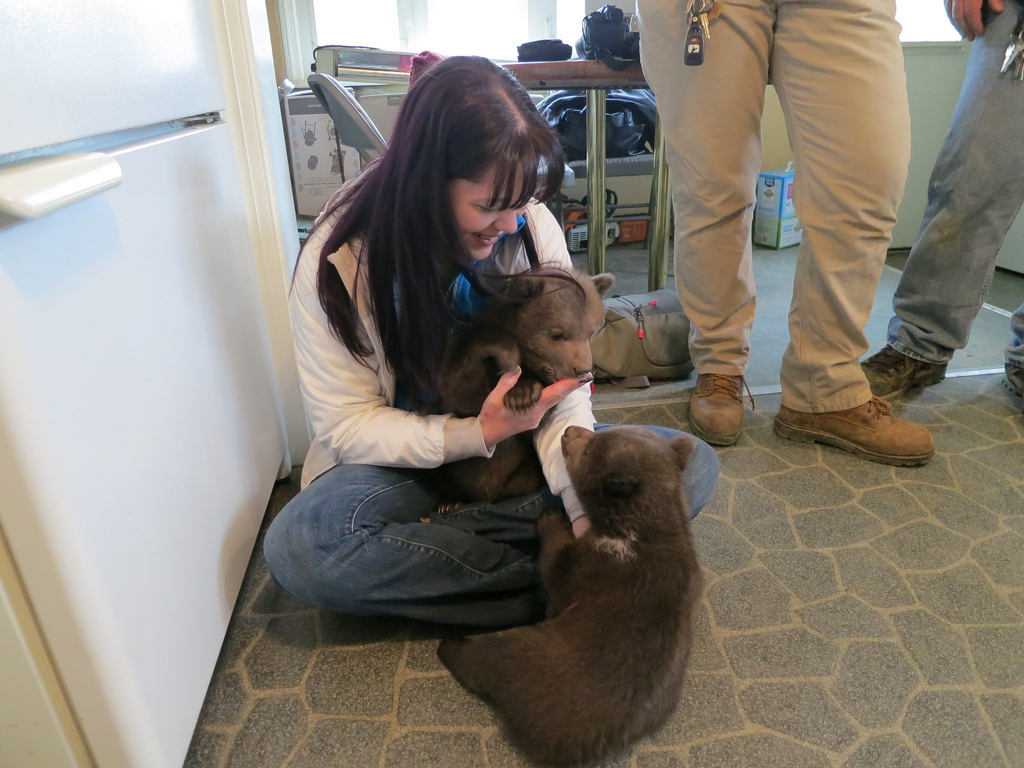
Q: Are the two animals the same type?
A: Yes, all the animals are bears.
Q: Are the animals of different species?
A: No, all the animals are bears.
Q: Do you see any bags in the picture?
A: Yes, there is a bag.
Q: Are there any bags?
A: Yes, there is a bag.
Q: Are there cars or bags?
A: Yes, there is a bag.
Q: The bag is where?
A: The bag is on the ground.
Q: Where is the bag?
A: The bag is on the ground.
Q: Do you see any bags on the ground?
A: Yes, there is a bag on the ground.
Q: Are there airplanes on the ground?
A: No, there is a bag on the ground.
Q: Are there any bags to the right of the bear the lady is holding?
A: Yes, there is a bag to the right of the bear.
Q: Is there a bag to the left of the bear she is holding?
A: No, the bag is to the right of the bear.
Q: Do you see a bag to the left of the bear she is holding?
A: No, the bag is to the right of the bear.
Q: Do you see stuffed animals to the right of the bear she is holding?
A: No, there is a bag to the right of the bear.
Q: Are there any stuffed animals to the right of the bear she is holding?
A: No, there is a bag to the right of the bear.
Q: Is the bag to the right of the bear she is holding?
A: Yes, the bag is to the right of the bear.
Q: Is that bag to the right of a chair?
A: No, the bag is to the right of the bear.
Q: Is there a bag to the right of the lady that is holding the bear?
A: Yes, there is a bag to the right of the lady.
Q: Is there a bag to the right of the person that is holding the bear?
A: Yes, there is a bag to the right of the lady.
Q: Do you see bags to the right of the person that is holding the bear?
A: Yes, there is a bag to the right of the lady.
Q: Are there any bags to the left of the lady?
A: No, the bag is to the right of the lady.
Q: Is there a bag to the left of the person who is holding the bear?
A: No, the bag is to the right of the lady.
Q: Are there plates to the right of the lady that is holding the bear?
A: No, there is a bag to the right of the lady.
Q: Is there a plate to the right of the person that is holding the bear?
A: No, there is a bag to the right of the lady.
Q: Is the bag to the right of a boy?
A: No, the bag is to the right of a lady.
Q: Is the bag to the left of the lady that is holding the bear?
A: No, the bag is to the right of the lady.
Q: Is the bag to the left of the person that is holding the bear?
A: No, the bag is to the right of the lady.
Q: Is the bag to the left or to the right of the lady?
A: The bag is to the right of the lady.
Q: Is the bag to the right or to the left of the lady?
A: The bag is to the right of the lady.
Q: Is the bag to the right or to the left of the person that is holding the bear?
A: The bag is to the right of the lady.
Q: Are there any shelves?
A: No, there are no shelves.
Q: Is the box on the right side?
A: Yes, the box is on the right of the image.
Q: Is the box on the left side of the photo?
A: No, the box is on the right of the image.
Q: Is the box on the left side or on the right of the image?
A: The box is on the right of the image.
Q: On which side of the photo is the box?
A: The box is on the right of the image.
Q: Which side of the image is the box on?
A: The box is on the right of the image.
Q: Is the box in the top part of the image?
A: Yes, the box is in the top of the image.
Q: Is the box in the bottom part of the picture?
A: No, the box is in the top of the image.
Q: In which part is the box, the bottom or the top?
A: The box is in the top of the image.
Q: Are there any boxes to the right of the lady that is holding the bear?
A: Yes, there is a box to the right of the lady.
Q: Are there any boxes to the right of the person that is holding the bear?
A: Yes, there is a box to the right of the lady.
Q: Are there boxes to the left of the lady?
A: No, the box is to the right of the lady.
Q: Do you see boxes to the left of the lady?
A: No, the box is to the right of the lady.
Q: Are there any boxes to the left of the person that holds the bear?
A: No, the box is to the right of the lady.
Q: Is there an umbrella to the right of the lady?
A: No, there is a box to the right of the lady.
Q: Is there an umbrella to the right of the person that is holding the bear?
A: No, there is a box to the right of the lady.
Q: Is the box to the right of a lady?
A: Yes, the box is to the right of a lady.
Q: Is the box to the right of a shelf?
A: No, the box is to the right of a lady.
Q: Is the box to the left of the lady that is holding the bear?
A: No, the box is to the right of the lady.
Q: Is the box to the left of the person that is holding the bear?
A: No, the box is to the right of the lady.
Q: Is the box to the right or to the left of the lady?
A: The box is to the right of the lady.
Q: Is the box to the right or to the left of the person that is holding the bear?
A: The box is to the right of the lady.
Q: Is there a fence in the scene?
A: No, there are no fences.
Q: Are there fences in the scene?
A: No, there are no fences.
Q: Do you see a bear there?
A: Yes, there is a bear.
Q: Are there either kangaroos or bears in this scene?
A: Yes, there is a bear.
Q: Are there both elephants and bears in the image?
A: No, there is a bear but no elephants.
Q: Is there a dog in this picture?
A: No, there are no dogs.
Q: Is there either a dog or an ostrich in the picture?
A: No, there are no dogs or ostriches.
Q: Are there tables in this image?
A: Yes, there is a table.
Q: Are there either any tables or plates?
A: Yes, there is a table.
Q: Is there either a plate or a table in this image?
A: Yes, there is a table.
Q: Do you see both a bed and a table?
A: No, there is a table but no beds.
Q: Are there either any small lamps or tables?
A: Yes, there is a small table.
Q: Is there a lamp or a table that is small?
A: Yes, the table is small.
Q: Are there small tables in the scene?
A: Yes, there is a small table.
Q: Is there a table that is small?
A: Yes, there is a table that is small.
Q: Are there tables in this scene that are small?
A: Yes, there is a table that is small.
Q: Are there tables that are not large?
A: Yes, there is a small table.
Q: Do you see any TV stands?
A: No, there are no TV stands.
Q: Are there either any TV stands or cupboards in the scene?
A: No, there are no TV stands or cupboards.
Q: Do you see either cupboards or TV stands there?
A: No, there are no TV stands or cupboards.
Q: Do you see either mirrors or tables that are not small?
A: No, there is a table but it is small.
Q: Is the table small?
A: Yes, the table is small.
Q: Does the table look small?
A: Yes, the table is small.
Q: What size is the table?
A: The table is small.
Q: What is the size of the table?
A: The table is small.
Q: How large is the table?
A: The table is small.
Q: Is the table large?
A: No, the table is small.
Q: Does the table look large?
A: No, the table is small.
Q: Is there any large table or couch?
A: No, there is a table but it is small.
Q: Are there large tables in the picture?
A: No, there is a table but it is small.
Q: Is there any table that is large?
A: No, there is a table but it is small.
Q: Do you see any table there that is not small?
A: No, there is a table but it is small.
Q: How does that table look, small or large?
A: The table is small.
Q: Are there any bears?
A: Yes, there is a bear.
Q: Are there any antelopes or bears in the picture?
A: Yes, there is a bear.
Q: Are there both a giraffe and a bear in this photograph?
A: No, there is a bear but no giraffes.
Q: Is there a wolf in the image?
A: No, there are no wolves.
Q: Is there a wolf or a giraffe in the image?
A: No, there are no wolves or giraffes.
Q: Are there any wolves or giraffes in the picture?
A: No, there are no wolves or giraffes.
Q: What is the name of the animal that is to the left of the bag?
A: The animal is a bear.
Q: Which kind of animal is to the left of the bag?
A: The animal is a bear.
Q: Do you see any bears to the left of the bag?
A: Yes, there is a bear to the left of the bag.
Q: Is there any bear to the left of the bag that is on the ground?
A: Yes, there is a bear to the left of the bag.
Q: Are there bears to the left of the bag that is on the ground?
A: Yes, there is a bear to the left of the bag.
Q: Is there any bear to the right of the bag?
A: No, the bear is to the left of the bag.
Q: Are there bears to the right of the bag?
A: No, the bear is to the left of the bag.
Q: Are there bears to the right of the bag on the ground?
A: No, the bear is to the left of the bag.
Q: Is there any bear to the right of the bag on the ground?
A: No, the bear is to the left of the bag.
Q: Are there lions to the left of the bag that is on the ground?
A: No, there is a bear to the left of the bag.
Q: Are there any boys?
A: No, there are no boys.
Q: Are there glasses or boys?
A: No, there are no boys or glasses.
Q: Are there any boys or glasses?
A: No, there are no boys or glasses.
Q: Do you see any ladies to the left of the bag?
A: Yes, there is a lady to the left of the bag.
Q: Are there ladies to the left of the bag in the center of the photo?
A: Yes, there is a lady to the left of the bag.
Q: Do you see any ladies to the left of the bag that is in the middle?
A: Yes, there is a lady to the left of the bag.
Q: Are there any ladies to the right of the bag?
A: No, the lady is to the left of the bag.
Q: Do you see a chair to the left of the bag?
A: No, there is a lady to the left of the bag.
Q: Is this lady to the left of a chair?
A: No, the lady is to the left of the bag.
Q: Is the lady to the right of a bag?
A: No, the lady is to the left of a bag.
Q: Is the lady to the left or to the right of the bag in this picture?
A: The lady is to the left of the bag.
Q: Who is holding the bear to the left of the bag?
A: The lady is holding the bear.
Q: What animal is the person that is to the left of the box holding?
A: The lady is holding the bear.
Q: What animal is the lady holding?
A: The lady is holding the bear.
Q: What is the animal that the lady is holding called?
A: The animal is a bear.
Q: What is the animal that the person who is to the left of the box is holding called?
A: The animal is a bear.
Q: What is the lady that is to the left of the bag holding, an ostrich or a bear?
A: The lady is holding a bear.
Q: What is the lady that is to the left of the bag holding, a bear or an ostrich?
A: The lady is holding a bear.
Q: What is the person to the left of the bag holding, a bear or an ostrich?
A: The lady is holding a bear.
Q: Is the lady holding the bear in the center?
A: Yes, the lady is holding the bear.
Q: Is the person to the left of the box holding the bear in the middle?
A: Yes, the lady is holding the bear.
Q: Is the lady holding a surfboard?
A: No, the lady is holding the bear.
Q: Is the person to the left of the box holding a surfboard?
A: No, the lady is holding the bear.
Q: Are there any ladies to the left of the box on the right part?
A: Yes, there is a lady to the left of the box.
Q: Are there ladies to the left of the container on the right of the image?
A: Yes, there is a lady to the left of the box.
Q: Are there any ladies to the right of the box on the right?
A: No, the lady is to the left of the box.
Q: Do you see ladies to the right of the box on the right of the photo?
A: No, the lady is to the left of the box.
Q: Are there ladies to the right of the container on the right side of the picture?
A: No, the lady is to the left of the box.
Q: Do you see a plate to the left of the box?
A: No, there is a lady to the left of the box.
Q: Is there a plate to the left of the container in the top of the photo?
A: No, there is a lady to the left of the box.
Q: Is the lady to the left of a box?
A: Yes, the lady is to the left of a box.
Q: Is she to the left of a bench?
A: No, the lady is to the left of a box.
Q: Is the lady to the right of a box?
A: No, the lady is to the left of a box.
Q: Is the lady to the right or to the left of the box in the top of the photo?
A: The lady is to the left of the box.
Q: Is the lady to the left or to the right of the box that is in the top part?
A: The lady is to the left of the box.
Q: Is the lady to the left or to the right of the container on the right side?
A: The lady is to the left of the box.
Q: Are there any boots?
A: Yes, there are boots.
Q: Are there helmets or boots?
A: Yes, there are boots.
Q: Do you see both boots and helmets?
A: No, there are boots but no helmets.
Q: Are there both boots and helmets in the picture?
A: No, there are boots but no helmets.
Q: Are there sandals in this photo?
A: No, there are no sandals.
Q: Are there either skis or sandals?
A: No, there are no sandals or skis.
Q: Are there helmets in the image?
A: No, there are no helmets.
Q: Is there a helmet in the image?
A: No, there are no helmets.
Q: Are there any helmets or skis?
A: No, there are no helmets or skis.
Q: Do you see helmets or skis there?
A: No, there are no helmets or skis.